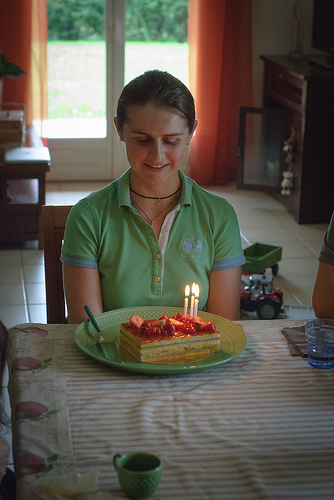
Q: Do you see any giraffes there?
A: No, there are no giraffes.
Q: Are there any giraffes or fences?
A: No, there are no giraffes or fences.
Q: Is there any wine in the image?
A: No, there is no wine.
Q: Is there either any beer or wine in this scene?
A: No, there are no wine or beer.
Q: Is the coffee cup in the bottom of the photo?
A: Yes, the coffee cup is in the bottom of the image.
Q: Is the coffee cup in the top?
A: No, the coffee cup is in the bottom of the image.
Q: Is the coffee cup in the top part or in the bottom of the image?
A: The coffee cup is in the bottom of the image.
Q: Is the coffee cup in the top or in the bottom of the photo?
A: The coffee cup is in the bottom of the image.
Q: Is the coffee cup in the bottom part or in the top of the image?
A: The coffee cup is in the bottom of the image.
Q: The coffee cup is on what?
A: The coffee cup is on the table.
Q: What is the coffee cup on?
A: The coffee cup is on the table.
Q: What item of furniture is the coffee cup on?
A: The coffee cup is on the table.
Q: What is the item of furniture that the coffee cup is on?
A: The piece of furniture is a table.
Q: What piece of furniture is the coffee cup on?
A: The coffee cup is on the table.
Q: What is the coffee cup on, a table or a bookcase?
A: The coffee cup is on a table.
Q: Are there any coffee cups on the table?
A: Yes, there is a coffee cup on the table.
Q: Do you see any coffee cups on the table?
A: Yes, there is a coffee cup on the table.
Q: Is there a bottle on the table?
A: No, there is a coffee cup on the table.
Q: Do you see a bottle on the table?
A: No, there is a coffee cup on the table.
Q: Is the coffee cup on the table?
A: Yes, the coffee cup is on the table.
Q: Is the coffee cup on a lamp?
A: No, the coffee cup is on the table.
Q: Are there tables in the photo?
A: Yes, there is a table.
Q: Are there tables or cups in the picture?
A: Yes, there is a table.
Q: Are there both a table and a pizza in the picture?
A: No, there is a table but no pizzas.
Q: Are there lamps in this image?
A: No, there are no lamps.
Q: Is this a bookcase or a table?
A: This is a table.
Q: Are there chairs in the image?
A: Yes, there is a chair.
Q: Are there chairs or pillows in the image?
A: Yes, there is a chair.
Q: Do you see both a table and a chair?
A: Yes, there are both a chair and a table.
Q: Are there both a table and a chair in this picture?
A: Yes, there are both a chair and a table.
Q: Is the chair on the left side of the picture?
A: Yes, the chair is on the left of the image.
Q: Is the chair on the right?
A: No, the chair is on the left of the image.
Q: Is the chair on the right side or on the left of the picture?
A: The chair is on the left of the image.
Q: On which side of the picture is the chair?
A: The chair is on the left of the image.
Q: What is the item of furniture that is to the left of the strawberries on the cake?
A: The piece of furniture is a chair.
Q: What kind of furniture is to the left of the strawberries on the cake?
A: The piece of furniture is a chair.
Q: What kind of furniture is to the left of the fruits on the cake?
A: The piece of furniture is a chair.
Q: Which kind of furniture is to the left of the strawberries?
A: The piece of furniture is a chair.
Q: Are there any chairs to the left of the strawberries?
A: Yes, there is a chair to the left of the strawberries.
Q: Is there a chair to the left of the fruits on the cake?
A: Yes, there is a chair to the left of the strawberries.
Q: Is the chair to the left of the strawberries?
A: Yes, the chair is to the left of the strawberries.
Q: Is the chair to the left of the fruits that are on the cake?
A: Yes, the chair is to the left of the strawberries.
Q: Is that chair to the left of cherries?
A: No, the chair is to the left of the strawberries.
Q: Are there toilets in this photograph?
A: No, there are no toilets.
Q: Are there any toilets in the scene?
A: No, there are no toilets.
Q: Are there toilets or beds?
A: No, there are no toilets or beds.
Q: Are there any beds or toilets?
A: No, there are no toilets or beds.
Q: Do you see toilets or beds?
A: No, there are no toilets or beds.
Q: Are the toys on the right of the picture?
A: Yes, the toys are on the right of the image.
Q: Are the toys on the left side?
A: No, the toys are on the right of the image.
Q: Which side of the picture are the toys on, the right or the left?
A: The toys are on the right of the image.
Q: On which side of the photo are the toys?
A: The toys are on the right of the image.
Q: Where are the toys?
A: The toys are on the floor.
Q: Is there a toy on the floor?
A: Yes, there are toys on the floor.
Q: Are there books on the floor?
A: No, there are toys on the floor.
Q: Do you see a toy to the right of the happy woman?
A: Yes, there are toys to the right of the woman.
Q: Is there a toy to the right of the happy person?
A: Yes, there are toys to the right of the woman.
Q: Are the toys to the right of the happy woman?
A: Yes, the toys are to the right of the woman.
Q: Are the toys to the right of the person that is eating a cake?
A: Yes, the toys are to the right of the woman.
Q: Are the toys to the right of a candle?
A: Yes, the toys are to the right of a candle.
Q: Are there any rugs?
A: No, there are no rugs.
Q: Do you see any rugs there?
A: No, there are no rugs.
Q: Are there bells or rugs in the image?
A: No, there are no rugs or bells.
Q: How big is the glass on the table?
A: The glass is small.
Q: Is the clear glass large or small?
A: The glass is small.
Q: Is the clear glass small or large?
A: The glass is small.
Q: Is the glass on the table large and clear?
A: No, the glass is clear but small.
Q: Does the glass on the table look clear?
A: Yes, the glass is clear.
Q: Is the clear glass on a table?
A: Yes, the glass is on a table.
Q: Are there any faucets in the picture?
A: No, there are no faucets.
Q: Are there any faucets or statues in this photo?
A: No, there are no faucets or statues.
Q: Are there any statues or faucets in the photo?
A: No, there are no faucets or statues.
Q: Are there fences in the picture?
A: No, there are no fences.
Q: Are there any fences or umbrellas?
A: No, there are no fences or umbrellas.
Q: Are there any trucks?
A: Yes, there is a truck.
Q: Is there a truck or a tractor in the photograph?
A: Yes, there is a truck.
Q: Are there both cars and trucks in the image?
A: No, there is a truck but no cars.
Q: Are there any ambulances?
A: No, there are no ambulances.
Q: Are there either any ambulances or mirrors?
A: No, there are no ambulances or mirrors.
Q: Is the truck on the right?
A: Yes, the truck is on the right of the image.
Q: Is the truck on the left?
A: No, the truck is on the right of the image.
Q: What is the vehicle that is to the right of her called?
A: The vehicle is a truck.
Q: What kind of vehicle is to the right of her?
A: The vehicle is a truck.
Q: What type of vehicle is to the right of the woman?
A: The vehicle is a truck.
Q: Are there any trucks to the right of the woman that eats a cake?
A: Yes, there is a truck to the right of the woman.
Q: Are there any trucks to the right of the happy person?
A: Yes, there is a truck to the right of the woman.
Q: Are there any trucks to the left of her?
A: No, the truck is to the right of the woman.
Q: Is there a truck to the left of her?
A: No, the truck is to the right of the woman.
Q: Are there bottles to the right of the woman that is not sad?
A: No, there is a truck to the right of the woman.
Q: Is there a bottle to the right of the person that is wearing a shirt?
A: No, there is a truck to the right of the woman.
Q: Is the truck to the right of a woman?
A: Yes, the truck is to the right of a woman.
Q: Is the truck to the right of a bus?
A: No, the truck is to the right of a woman.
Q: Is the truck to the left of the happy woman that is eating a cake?
A: No, the truck is to the right of the woman.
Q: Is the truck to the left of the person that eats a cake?
A: No, the truck is to the right of the woman.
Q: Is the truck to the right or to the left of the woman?
A: The truck is to the right of the woman.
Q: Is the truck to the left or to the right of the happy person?
A: The truck is to the right of the woman.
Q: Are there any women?
A: Yes, there is a woman.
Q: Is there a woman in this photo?
A: Yes, there is a woman.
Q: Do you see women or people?
A: Yes, there is a woman.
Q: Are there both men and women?
A: No, there is a woman but no men.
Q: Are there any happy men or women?
A: Yes, there is a happy woman.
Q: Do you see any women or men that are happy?
A: Yes, the woman is happy.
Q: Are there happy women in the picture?
A: Yes, there is a happy woman.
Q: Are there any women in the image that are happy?
A: Yes, there is a woman that is happy.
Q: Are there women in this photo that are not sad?
A: Yes, there is a happy woman.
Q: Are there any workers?
A: No, there are no workers.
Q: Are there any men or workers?
A: No, there are no workers or men.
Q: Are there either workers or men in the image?
A: No, there are no workers or men.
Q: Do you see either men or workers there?
A: No, there are no workers or men.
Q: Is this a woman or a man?
A: This is a woman.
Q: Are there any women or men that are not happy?
A: No, there is a woman but she is happy.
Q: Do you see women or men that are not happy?
A: No, there is a woman but she is happy.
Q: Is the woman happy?
A: Yes, the woman is happy.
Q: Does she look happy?
A: Yes, the woman is happy.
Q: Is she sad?
A: No, the woman is happy.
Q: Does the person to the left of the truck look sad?
A: No, the woman is happy.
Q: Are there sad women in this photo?
A: No, there is a woman but she is happy.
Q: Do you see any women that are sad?
A: No, there is a woman but she is happy.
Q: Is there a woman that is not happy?
A: No, there is a woman but she is happy.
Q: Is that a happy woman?
A: Yes, that is a happy woman.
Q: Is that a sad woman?
A: No, that is a happy woman.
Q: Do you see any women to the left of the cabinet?
A: Yes, there is a woman to the left of the cabinet.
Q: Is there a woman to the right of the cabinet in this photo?
A: No, the woman is to the left of the cabinet.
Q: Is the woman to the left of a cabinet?
A: Yes, the woman is to the left of a cabinet.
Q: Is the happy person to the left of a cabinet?
A: Yes, the woman is to the left of a cabinet.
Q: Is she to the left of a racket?
A: No, the woman is to the left of a cabinet.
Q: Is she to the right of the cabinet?
A: No, the woman is to the left of the cabinet.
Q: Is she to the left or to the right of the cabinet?
A: The woman is to the left of the cabinet.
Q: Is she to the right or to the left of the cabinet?
A: The woman is to the left of the cabinet.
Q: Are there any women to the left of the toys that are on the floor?
A: Yes, there is a woman to the left of the toys.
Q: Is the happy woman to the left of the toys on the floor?
A: Yes, the woman is to the left of the toys.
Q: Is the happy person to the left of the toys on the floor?
A: Yes, the woman is to the left of the toys.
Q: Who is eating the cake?
A: The woman is eating the cake.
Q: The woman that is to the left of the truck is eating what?
A: The woman is eating a cake.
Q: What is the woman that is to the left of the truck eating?
A: The woman is eating a cake.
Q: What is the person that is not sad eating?
A: The woman is eating a cake.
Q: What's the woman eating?
A: The woman is eating a cake.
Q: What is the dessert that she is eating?
A: The dessert is a cake.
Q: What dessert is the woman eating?
A: The woman is eating a cake.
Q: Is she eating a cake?
A: Yes, the woman is eating a cake.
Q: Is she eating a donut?
A: No, the woman is eating a cake.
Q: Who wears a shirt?
A: The woman wears a shirt.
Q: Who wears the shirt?
A: The woman wears a shirt.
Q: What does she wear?
A: The woman wears a shirt.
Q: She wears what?
A: The woman wears a shirt.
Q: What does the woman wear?
A: The woman wears a shirt.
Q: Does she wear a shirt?
A: Yes, the woman wears a shirt.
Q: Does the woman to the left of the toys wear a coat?
A: No, the woman wears a shirt.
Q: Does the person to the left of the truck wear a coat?
A: No, the woman wears a shirt.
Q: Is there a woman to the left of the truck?
A: Yes, there is a woman to the left of the truck.